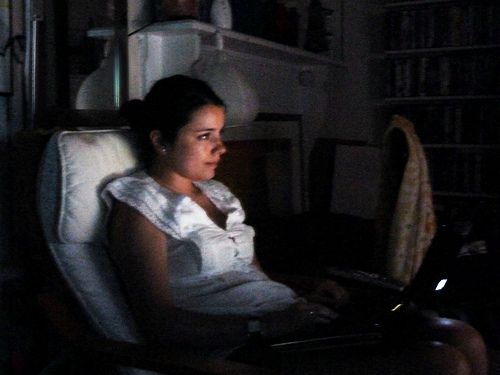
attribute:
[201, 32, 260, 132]
lamp — white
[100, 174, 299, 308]
blouse — white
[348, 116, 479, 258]
blanket — yellow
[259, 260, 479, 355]
laptop — computer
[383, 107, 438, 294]
blanket — colorful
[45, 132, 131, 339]
pillow — white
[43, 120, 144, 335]
pillow — white 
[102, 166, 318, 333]
blouse — white, short-sleeved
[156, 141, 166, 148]
earring — small, diamond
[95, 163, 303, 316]
shirt — white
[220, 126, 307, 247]
fireplace — unused, white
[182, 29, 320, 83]
shelf — white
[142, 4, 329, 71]
shelf — wooden, white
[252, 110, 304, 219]
frame — brown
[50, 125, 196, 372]
chair — white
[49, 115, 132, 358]
chair — white 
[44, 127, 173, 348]
cushion — white